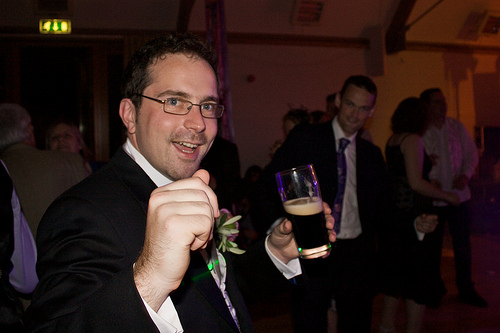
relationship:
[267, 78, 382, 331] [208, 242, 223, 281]
man with tie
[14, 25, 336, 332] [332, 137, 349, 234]
man with tie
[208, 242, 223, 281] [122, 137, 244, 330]
tie on shirt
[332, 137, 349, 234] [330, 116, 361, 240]
tie on shirt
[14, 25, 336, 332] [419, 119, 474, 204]
man wearing white shirt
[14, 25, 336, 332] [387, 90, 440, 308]
man stands next to lady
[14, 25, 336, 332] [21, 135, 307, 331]
man wearing suit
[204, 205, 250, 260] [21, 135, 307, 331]
corsage on suit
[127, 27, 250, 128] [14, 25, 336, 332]
hair on man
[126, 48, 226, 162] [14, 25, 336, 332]
head of man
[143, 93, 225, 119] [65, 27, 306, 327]
eyeglasses on person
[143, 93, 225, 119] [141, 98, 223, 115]
eyeglasses of glasses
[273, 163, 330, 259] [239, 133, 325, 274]
glass in hand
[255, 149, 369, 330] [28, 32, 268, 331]
hand of man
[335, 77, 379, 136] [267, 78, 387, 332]
head of man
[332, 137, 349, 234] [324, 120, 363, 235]
tie on shirt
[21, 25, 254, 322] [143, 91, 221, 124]
man wearing eyeglasses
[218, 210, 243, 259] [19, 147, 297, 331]
carnation on blazer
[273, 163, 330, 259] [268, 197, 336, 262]
glass in hand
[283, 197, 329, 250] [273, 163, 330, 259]
beer in glass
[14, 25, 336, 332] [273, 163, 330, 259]
man holding glass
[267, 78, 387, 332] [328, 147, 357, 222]
man wearing tie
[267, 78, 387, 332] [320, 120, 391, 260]
man wearing shirt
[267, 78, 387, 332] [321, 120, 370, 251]
man wearing tie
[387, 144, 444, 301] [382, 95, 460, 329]
black dress on lady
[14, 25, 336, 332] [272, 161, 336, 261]
man holds glass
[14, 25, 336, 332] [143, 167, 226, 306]
man has hand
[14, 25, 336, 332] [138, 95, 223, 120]
man wears glasses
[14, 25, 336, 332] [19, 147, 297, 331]
man wears blazer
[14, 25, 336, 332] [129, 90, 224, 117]
man wears glasses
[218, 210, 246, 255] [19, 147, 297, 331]
carnation on blazer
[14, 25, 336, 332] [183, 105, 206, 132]
man has nose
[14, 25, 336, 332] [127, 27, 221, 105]
man has hair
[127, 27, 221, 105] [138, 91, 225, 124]
hair has glasses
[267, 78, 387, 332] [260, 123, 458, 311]
man wearing blazer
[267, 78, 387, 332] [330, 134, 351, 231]
man wearing tie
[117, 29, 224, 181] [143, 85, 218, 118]
face wears glasses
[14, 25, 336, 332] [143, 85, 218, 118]
man wears glasses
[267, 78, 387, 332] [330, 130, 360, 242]
man wears tie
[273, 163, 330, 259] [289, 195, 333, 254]
glass holds beer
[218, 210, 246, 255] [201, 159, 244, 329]
carnation on shirt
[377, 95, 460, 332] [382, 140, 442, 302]
lady wears a black dress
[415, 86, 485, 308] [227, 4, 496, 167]
man in background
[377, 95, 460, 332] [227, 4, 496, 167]
lady in background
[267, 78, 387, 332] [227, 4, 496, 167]
man in background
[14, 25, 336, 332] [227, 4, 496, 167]
man in background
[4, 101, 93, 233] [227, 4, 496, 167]
man in background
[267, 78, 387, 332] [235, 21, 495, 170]
man in background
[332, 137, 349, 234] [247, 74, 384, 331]
tie on man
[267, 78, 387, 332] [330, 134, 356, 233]
man wearing tie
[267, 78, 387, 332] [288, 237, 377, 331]
man wearing pants